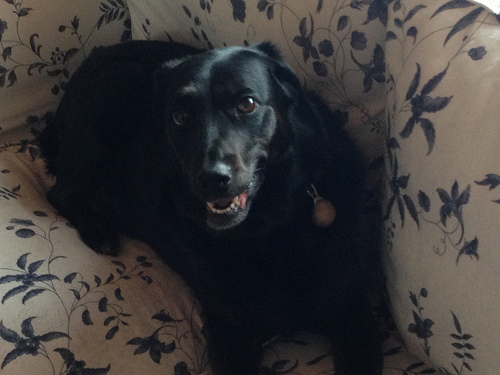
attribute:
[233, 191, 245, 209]
tongue — black, dog's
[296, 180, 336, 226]
tag — dog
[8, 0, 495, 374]
couch — white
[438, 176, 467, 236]
floral design — blue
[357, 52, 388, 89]
floral design — blue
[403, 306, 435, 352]
floral design — blue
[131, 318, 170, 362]
floral design — blue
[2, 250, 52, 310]
floral design — blue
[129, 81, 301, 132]
eyes — dog, alert, sparkly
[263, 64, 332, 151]
left ear — black, dog's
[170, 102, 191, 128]
eye — dog's, black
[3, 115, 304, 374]
sofa cushion — bamboo, patterned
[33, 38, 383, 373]
dog — black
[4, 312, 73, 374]
flower — blue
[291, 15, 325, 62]
flower — blue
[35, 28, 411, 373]
dog — happy, smiling, black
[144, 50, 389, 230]
dog — black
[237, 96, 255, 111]
eye — dog's, brown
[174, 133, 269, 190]
nose — black, dog's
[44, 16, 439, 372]
dog — black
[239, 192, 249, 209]
gum — pink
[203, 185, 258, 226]
mouth — dog's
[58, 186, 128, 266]
paw — back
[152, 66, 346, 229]
collar — dog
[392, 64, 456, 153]
flower — blue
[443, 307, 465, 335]
leaf — blue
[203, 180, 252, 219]
teeth — dog's, bottom row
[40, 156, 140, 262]
leg — hind